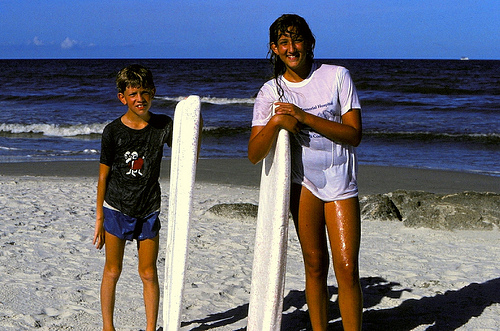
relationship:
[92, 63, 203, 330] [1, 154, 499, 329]
person on beach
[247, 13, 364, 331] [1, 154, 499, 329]
person on beach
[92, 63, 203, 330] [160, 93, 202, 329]
person beside surfboard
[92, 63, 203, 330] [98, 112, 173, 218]
person wearing shirt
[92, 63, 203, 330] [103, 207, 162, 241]
person wearing shorts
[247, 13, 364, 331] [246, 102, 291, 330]
person leaning on surfboard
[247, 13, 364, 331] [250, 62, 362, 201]
person wearing shirt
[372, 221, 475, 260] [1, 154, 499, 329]
rocks on beach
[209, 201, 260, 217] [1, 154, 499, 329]
rocks on beach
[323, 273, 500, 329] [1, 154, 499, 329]
shadow on beach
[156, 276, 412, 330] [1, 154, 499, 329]
shadow on beach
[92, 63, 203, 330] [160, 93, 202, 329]
person with surfboard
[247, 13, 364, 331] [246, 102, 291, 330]
person with surfboard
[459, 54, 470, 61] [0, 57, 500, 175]
boat on water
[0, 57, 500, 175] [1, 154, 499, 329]
water rolling in on beach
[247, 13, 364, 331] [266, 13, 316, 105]
person has hair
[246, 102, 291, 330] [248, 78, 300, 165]
surfboard under arm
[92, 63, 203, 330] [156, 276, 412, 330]
person has shadow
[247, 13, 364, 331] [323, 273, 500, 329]
person has shadow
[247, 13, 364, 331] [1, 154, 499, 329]
person standing on beach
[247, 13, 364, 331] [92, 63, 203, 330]
person right of person